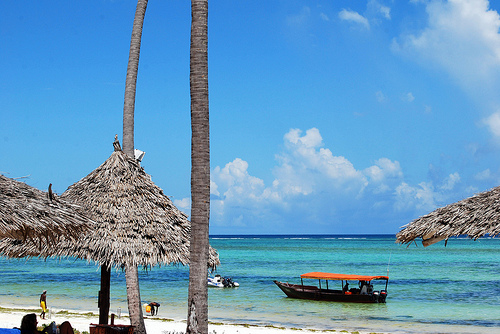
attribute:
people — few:
[330, 279, 369, 298]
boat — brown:
[261, 262, 401, 318]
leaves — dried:
[68, 166, 167, 268]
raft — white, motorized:
[210, 275, 234, 292]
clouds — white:
[168, 120, 425, 237]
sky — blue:
[3, 3, 495, 210]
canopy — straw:
[63, 141, 225, 301]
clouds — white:
[172, 0, 498, 228]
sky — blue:
[1, 0, 499, 233]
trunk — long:
[114, 0, 154, 332]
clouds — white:
[239, 116, 405, 202]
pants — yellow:
[37, 299, 48, 313]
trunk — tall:
[185, 1, 220, 332]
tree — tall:
[185, 3, 214, 332]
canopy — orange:
[300, 269, 390, 281]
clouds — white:
[220, 139, 413, 219]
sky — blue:
[321, 48, 351, 63]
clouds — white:
[236, 83, 310, 142]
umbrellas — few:
[2, 138, 213, 318]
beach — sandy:
[1, 299, 346, 331]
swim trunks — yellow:
[41, 299, 48, 313]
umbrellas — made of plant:
[2, 146, 234, 275]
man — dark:
[35, 293, 57, 315]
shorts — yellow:
[35, 296, 56, 312]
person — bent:
[144, 301, 162, 318]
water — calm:
[2, 222, 499, 323]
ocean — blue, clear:
[282, 228, 414, 273]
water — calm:
[307, 230, 407, 261]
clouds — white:
[211, 124, 426, 239]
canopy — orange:
[300, 271, 388, 281]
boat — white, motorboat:
[176, 260, 243, 308]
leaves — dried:
[65, 197, 149, 240]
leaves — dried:
[81, 170, 188, 252]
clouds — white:
[260, 125, 415, 212]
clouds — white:
[215, 135, 417, 242]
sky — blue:
[126, 44, 414, 227]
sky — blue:
[73, 27, 443, 219]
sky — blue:
[97, 37, 456, 232]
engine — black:
[213, 275, 243, 290]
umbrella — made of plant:
[55, 149, 221, 270]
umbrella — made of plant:
[0, 175, 81, 258]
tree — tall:
[120, 3, 148, 332]